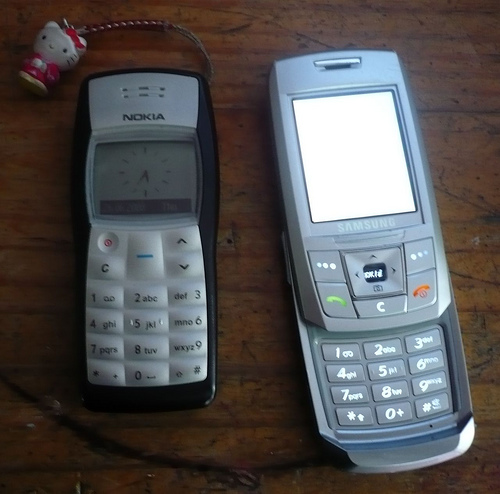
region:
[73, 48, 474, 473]
the two cell phones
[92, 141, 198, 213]
the screen on the cell phone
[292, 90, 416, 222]
the screen on the cell phone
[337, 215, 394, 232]
the word SAMSUNG on the phone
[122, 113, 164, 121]
the word NOKIA on the phone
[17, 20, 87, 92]
the hello kitty charm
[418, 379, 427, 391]
the number "9" on the cell phone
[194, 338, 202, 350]
the number "9" on the cell phone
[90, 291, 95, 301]
the number "1" on the cell phone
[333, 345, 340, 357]
the number "1" on the cell phone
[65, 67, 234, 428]
small nokia phone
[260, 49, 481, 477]
sumsung phone that slides up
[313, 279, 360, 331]
green call button on a phone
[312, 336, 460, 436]
phone keyboard with white letters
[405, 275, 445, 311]
red hangup button on a phone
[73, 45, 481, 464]
two old phones on a brown counter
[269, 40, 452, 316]
lit screen on a phone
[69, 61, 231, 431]
gray and black nokia phone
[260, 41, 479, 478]
gray cell phone on a brown surface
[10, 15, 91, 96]
tiny toy on a brown surface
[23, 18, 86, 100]
hello kitty attached to a cellphone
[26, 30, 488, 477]
two cellphones on a table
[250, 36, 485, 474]
Cellphone on the table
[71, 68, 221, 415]
Cellphone on the table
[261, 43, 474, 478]
Cellphone on the table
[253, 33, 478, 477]
Cellphone on the table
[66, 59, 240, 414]
Cellphone on the table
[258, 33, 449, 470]
Cellphone on the table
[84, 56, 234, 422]
Cellphone on the table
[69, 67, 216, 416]
Cellphone on the table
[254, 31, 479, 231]
light on the phone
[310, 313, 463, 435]
buttons on the phone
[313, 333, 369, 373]
number on the phone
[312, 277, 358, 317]
green button on phone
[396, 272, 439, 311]
red button on phone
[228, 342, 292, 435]
table under the phone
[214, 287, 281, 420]
brown table in photo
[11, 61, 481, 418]
two phones in photo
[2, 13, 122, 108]
object next to phones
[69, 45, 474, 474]
the two cell phones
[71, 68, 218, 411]
the NOKIA cell phone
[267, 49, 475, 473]
the SAMSUNG cell phone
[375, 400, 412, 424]
the "0" button on the cell phone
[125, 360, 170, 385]
the "0" button on the cell phone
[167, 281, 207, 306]
the number "3" button on the cell phone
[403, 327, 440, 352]
the number "3" button on the cell phone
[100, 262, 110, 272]
the letter "C" on the cell phone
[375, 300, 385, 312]
the letter "C" on the cell phone